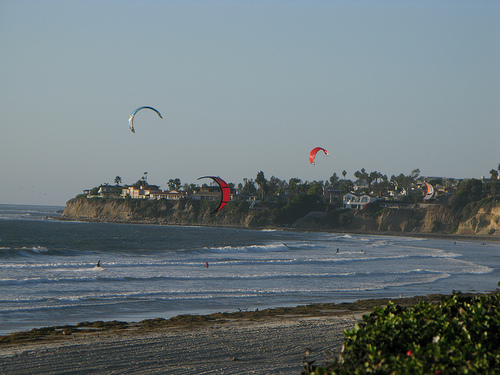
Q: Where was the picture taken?
A: At the beach.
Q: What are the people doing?
A: Flying kites.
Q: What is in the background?
A: Houses.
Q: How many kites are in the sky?
A: Three.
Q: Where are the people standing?
A: In the water.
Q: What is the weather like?
A: Clear and sunny.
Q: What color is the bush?
A: Green.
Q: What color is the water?
A: Blue.